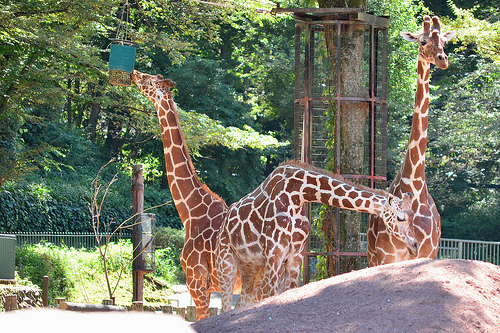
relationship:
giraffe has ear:
[214, 156, 419, 316] [386, 193, 395, 212]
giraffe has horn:
[214, 156, 419, 316] [399, 192, 412, 209]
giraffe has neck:
[214, 156, 419, 316] [295, 165, 389, 222]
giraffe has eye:
[214, 156, 419, 316] [396, 215, 406, 222]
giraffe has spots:
[214, 156, 419, 316] [236, 202, 299, 251]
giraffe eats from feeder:
[129, 69, 266, 320] [107, 42, 138, 86]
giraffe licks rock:
[214, 156, 419, 316] [189, 257, 500, 331]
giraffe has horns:
[366, 12, 455, 269] [420, 13, 440, 35]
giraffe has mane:
[214, 156, 419, 316] [278, 158, 390, 197]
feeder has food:
[107, 42, 138, 86] [108, 69, 135, 86]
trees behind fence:
[1, 1, 500, 243] [2, 225, 500, 332]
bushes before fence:
[14, 238, 180, 302] [2, 225, 500, 332]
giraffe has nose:
[214, 156, 419, 316] [407, 241, 420, 260]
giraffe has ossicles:
[214, 156, 419, 316] [399, 192, 412, 209]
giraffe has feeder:
[129, 69, 266, 320] [107, 42, 138, 86]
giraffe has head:
[129, 69, 266, 320] [131, 69, 178, 101]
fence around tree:
[2, 225, 500, 332] [88, 157, 175, 307]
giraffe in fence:
[366, 14, 448, 269] [2, 225, 500, 332]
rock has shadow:
[189, 257, 500, 331] [191, 272, 464, 333]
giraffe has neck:
[129, 69, 266, 320] [156, 98, 216, 219]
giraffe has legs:
[129, 69, 266, 320] [180, 243, 217, 324]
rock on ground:
[188, 257, 500, 331] [1, 7, 500, 260]